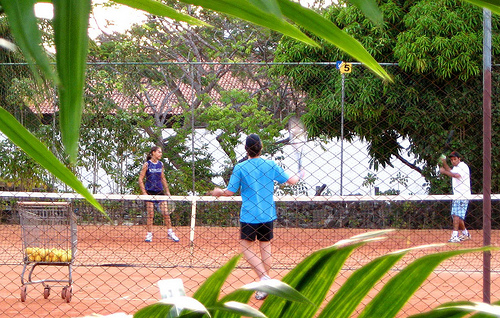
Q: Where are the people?
A: In a tennis court.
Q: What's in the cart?
A: Tennis balls.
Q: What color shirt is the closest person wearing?
A: Blue.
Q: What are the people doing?
A: Playing tennis.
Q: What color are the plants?
A: Green.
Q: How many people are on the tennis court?
A: Three.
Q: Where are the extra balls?
A: In the cart.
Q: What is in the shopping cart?
A: Extra tennis balls.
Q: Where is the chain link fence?
A: Behind the players.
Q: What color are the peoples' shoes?
A: White.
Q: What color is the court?
A: Reddish brown.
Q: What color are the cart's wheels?
A: Brown.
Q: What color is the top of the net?
A: White.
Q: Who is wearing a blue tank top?
A: A girl.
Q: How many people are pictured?
A: Three.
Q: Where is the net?
A: On the tennis court.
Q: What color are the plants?
A: Green.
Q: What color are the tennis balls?
A: Yellow.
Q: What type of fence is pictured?
A: A chain link fence.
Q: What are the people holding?
A: Tennis racquets.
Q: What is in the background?
A: A building.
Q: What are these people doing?
A: Playing tennis.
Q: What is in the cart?
A: Tennis balls.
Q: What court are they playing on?
A: 5.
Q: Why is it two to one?
A: One player is a teacher.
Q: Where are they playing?
A: On a court.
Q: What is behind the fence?
A: Green trees.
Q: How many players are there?
A: Three.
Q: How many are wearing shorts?
A: Three.